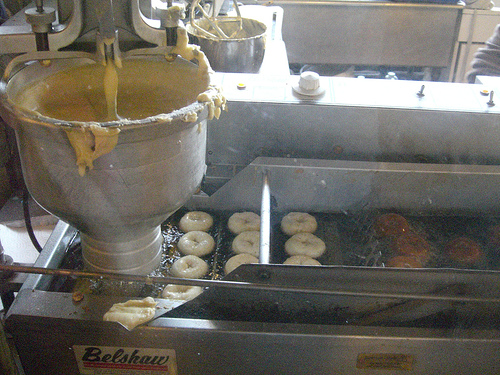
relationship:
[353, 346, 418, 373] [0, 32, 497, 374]
sticker on machine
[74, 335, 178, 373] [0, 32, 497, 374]
name printed on machine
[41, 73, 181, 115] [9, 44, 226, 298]
batter inside mixing bowl